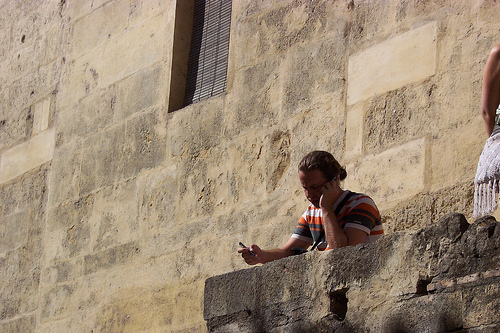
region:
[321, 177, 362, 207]
A person talking on the cell phone.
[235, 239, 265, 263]
The person is holding a pen.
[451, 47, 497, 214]
A person is standing by the building.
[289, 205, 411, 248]
The shirt is striped.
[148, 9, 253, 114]
A window on the building.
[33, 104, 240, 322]
The building is stone.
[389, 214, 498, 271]
The edge of the balcony is rocks.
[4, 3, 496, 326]
wall made of stone blocks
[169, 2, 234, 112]
window with closed blind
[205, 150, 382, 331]
man behind stone wall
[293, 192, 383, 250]
striped shirt with short sleeves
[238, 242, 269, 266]
pen in man's hand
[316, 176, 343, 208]
phone held against head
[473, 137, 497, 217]
fabric with hanging tassels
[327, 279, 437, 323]
two holes in wall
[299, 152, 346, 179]
brown hair on head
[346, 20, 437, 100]
light tan rectangle stone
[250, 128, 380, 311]
a man on a phone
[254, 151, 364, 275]
a man on a cell phone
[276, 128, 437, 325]
a man talking on a phone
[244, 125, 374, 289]
a man talking on cell phone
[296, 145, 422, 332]
a man holding a phone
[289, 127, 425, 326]
a man holding a cell phone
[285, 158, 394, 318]
a man standing outside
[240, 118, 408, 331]
a man wearing a shirt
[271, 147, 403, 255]
a man wearing a striped shirt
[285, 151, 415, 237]
a man with long hair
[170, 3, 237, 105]
a window above the man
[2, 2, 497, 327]
large brick building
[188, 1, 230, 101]
brown wooden blinds in window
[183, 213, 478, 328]
a stone balcony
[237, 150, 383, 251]
a man talking on a cellphone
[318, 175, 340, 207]
cellphone in left hand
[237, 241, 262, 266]
a pen in the right hand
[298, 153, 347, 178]
the man's hair is slicked back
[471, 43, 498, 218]
a woman on the left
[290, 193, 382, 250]
an orange, blue, and white stripped shirt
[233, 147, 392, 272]
man talking on a phone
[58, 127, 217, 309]
cement block facade on a building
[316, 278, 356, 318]
drain hole on a wall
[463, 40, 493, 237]
woman standing by a wall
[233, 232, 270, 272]
right hand of a man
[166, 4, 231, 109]
window on a building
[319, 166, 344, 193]
phone in man's hand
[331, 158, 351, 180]
ponytail on a man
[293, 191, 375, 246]
striped short sleeve shirt on a man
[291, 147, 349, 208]
face of a man